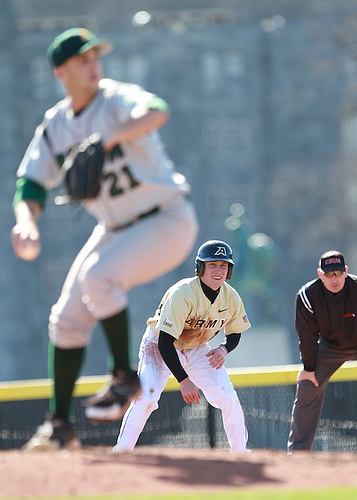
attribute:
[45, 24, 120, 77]
helmet — present, blue, green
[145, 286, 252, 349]
shirt — green, brown, tan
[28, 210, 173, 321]
pants — grey, white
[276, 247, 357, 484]
umpire — black, present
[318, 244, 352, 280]
hat — green, blurry, black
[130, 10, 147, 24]
ball — thrown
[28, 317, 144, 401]
socks — green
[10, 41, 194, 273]
player — dirty, holding, casting, standing, playing, present, shadowed, glassed, pitching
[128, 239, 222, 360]
uniform — dirty, nike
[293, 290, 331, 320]
stripes — white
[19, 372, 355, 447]
fence — black, chained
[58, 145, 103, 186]
glove — black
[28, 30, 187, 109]
man — wearing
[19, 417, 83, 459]
shoe — present